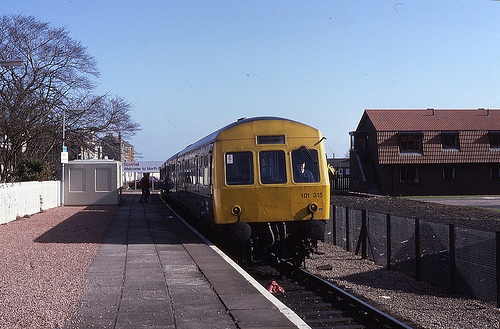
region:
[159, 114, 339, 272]
The train is yellow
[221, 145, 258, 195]
Train has rear window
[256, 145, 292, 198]
Train has rear window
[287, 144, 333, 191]
Train has rear window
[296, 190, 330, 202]
Train is number 101 315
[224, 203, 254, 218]
Train has rear light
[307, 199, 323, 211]
Train has a rear light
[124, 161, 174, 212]
People waiting to board train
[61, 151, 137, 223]
White building next to platform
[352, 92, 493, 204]
Brown building at train station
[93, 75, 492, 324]
a yellow train on a track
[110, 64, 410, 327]
a yellow train going down a track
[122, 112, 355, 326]
a train track with a train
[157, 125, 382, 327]
a train track with a yellow train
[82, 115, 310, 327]
a sidewalk next to the train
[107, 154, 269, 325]
a sidewalk next to the train tracks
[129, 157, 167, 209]
a person standing on the sidewalk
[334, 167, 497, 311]
a fence next to the train tracks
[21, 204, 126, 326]
rocks next to the sidewalk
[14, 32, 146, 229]
trees with no leaves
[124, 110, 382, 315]
train in the train tracks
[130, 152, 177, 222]
the people are standing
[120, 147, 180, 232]
people at the platform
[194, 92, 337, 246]
front of train is yellow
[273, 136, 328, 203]
an engineer in the train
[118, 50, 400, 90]
the sky is clear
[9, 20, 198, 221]
the trees are bare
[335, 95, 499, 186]
the train station is brown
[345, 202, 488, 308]
fence beside the train tracks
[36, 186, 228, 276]
shadows on the ground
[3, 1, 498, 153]
the sky is blue.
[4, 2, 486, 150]
the sky is clear.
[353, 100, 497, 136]
the roof is brown.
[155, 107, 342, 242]
the train is yellow.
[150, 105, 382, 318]
train on the tracks.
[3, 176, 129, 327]
the gravel is brown.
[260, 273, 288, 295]
red object on the tracks.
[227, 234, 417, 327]
the train tracks are black.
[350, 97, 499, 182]
the building is brown.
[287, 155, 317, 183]
train conductor in the window.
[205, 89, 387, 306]
the train is on tracks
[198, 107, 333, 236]
the train is yellow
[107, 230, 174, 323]
the concrete is gray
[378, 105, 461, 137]
the roof is red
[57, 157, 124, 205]
the building is small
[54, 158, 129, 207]
the building is white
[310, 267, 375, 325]
the tracks are metal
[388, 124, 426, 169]
the building has a window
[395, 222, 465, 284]
the fence is small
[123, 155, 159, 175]
the banner is white